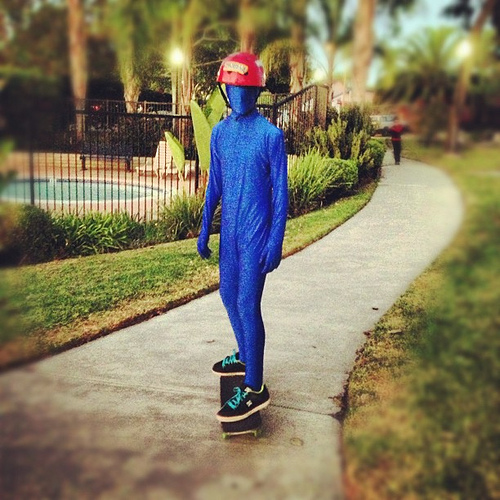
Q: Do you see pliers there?
A: No, there are no pliers.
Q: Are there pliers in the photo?
A: No, there are no pliers.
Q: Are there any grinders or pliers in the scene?
A: No, there are no pliers or grinders.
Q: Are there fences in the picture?
A: Yes, there is a fence.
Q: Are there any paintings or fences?
A: Yes, there is a fence.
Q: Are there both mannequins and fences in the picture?
A: No, there is a fence but no mannequins.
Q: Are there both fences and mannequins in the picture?
A: No, there is a fence but no mannequins.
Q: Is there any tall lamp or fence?
A: Yes, there is a tall fence.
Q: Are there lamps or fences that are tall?
A: Yes, the fence is tall.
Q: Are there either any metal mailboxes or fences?
A: Yes, there is a metal fence.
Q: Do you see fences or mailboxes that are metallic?
A: Yes, the fence is metallic.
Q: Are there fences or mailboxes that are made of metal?
A: Yes, the fence is made of metal.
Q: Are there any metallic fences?
A: Yes, there is a metal fence.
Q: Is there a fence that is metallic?
A: Yes, there is a fence that is metallic.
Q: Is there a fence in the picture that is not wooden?
A: Yes, there is a metallic fence.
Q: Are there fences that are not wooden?
A: Yes, there is a metallic fence.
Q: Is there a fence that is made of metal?
A: Yes, there is a fence that is made of metal.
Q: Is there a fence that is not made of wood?
A: Yes, there is a fence that is made of metal.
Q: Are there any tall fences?
A: Yes, there is a tall fence.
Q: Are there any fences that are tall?
A: Yes, there is a fence that is tall.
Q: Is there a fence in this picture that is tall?
A: Yes, there is a fence that is tall.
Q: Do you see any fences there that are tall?
A: Yes, there is a fence that is tall.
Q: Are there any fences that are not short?
A: Yes, there is a tall fence.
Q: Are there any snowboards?
A: No, there are no snowboards.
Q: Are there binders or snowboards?
A: No, there are no snowboards or binders.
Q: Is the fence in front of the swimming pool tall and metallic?
A: Yes, the fence is tall and metallic.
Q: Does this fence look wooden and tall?
A: No, the fence is tall but metallic.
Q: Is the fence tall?
A: Yes, the fence is tall.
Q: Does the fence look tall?
A: Yes, the fence is tall.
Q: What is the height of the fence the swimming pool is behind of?
A: The fence is tall.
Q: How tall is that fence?
A: The fence is tall.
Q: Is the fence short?
A: No, the fence is tall.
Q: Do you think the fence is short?
A: No, the fence is tall.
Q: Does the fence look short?
A: No, the fence is tall.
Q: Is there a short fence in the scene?
A: No, there is a fence but it is tall.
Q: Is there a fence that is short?
A: No, there is a fence but it is tall.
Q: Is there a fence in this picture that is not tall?
A: No, there is a fence but it is tall.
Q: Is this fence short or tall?
A: The fence is tall.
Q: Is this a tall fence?
A: Yes, this is a tall fence.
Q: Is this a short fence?
A: No, this is a tall fence.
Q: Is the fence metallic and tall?
A: Yes, the fence is metallic and tall.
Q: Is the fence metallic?
A: Yes, the fence is metallic.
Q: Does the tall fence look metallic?
A: Yes, the fence is metallic.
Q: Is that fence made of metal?
A: Yes, the fence is made of metal.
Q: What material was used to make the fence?
A: The fence is made of metal.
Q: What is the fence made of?
A: The fence is made of metal.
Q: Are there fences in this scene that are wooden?
A: No, there is a fence but it is metallic.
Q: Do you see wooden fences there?
A: No, there is a fence but it is metallic.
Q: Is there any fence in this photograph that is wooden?
A: No, there is a fence but it is metallic.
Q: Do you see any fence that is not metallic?
A: No, there is a fence but it is metallic.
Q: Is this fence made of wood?
A: No, the fence is made of metal.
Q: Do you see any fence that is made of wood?
A: No, there is a fence but it is made of metal.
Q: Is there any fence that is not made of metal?
A: No, there is a fence but it is made of metal.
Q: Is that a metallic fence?
A: Yes, that is a metallic fence.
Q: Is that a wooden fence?
A: No, that is a metallic fence.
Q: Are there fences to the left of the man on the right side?
A: Yes, there is a fence to the left of the man.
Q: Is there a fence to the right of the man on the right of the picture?
A: No, the fence is to the left of the man.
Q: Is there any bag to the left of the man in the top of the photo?
A: No, there is a fence to the left of the man.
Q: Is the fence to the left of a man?
A: Yes, the fence is to the left of a man.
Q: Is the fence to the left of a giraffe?
A: No, the fence is to the left of a man.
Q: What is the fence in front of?
A: The fence is in front of the pool.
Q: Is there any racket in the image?
A: No, there are no rackets.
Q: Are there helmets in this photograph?
A: Yes, there is a helmet.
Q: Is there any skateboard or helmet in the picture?
A: Yes, there is a helmet.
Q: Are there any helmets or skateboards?
A: Yes, there is a helmet.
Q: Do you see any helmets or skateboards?
A: Yes, there is a helmet.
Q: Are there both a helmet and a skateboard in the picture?
A: Yes, there are both a helmet and a skateboard.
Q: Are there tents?
A: No, there are no tents.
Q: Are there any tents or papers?
A: No, there are no tents or papers.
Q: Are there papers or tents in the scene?
A: No, there are no tents or papers.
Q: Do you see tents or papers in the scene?
A: No, there are no tents or papers.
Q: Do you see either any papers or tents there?
A: No, there are no tents or papers.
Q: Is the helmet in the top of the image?
A: Yes, the helmet is in the top of the image.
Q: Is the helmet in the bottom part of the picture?
A: No, the helmet is in the top of the image.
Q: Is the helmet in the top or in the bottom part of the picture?
A: The helmet is in the top of the image.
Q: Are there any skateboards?
A: Yes, there is a skateboard.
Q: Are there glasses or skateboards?
A: Yes, there is a skateboard.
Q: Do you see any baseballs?
A: No, there are no baseballs.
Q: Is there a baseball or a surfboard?
A: No, there are no baseballs or surfboards.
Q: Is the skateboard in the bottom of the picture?
A: Yes, the skateboard is in the bottom of the image.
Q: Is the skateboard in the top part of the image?
A: No, the skateboard is in the bottom of the image.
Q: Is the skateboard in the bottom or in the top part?
A: The skateboard is in the bottom of the image.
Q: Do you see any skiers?
A: No, there are no skiers.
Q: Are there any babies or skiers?
A: No, there are no skiers or babies.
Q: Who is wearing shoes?
A: The man is wearing shoes.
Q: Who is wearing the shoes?
A: The man is wearing shoes.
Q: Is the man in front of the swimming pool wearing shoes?
A: Yes, the man is wearing shoes.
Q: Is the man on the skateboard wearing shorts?
A: No, the man is wearing shoes.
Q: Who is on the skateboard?
A: The man is on the skateboard.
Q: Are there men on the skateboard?
A: Yes, there is a man on the skateboard.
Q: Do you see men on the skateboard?
A: Yes, there is a man on the skateboard.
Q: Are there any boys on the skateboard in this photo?
A: No, there is a man on the skateboard.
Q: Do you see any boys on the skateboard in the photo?
A: No, there is a man on the skateboard.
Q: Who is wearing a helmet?
A: The man is wearing a helmet.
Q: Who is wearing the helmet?
A: The man is wearing a helmet.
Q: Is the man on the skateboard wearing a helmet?
A: Yes, the man is wearing a helmet.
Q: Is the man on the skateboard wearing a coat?
A: No, the man is wearing a helmet.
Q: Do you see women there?
A: No, there are no women.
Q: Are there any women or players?
A: No, there are no women or players.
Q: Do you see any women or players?
A: No, there are no women or players.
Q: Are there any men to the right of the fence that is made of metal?
A: Yes, there is a man to the right of the fence.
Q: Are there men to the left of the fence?
A: No, the man is to the right of the fence.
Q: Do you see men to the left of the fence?
A: No, the man is to the right of the fence.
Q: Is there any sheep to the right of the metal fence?
A: No, there is a man to the right of the fence.